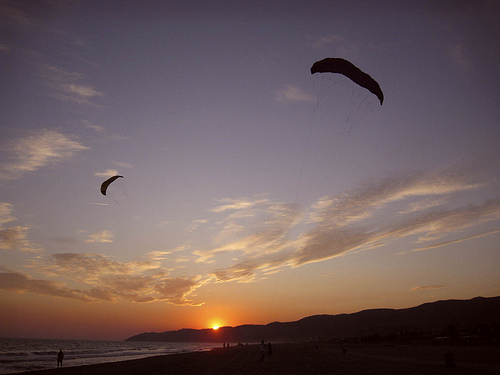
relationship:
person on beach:
[55, 346, 64, 368] [0, 339, 498, 374]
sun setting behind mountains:
[210, 317, 224, 331] [121, 294, 499, 341]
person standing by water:
[55, 346, 64, 368] [0, 338, 237, 373]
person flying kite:
[267, 340, 274, 357] [309, 57, 385, 107]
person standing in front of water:
[55, 346, 64, 368] [0, 338, 237, 373]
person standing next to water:
[55, 346, 64, 368] [0, 338, 237, 373]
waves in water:
[0, 349, 47, 361] [0, 338, 237, 373]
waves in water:
[108, 345, 158, 353] [0, 338, 237, 373]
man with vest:
[258, 337, 264, 360] [260, 344, 264, 350]